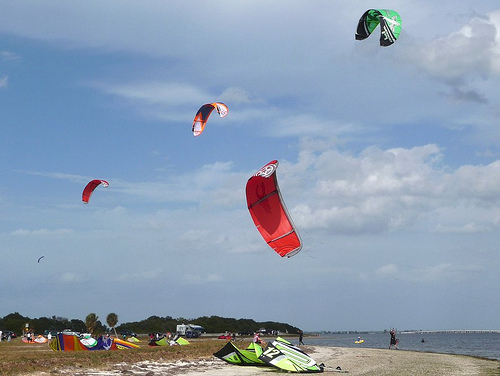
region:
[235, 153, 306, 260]
Red kite in the sky.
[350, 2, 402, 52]
Green and black kite in the sky.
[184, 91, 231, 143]
Orange kite in the sky.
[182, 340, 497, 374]
Sand on the ground.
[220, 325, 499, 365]
Water in the background.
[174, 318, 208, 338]
RV camper in the backgrund.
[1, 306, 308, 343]
Trees in the background.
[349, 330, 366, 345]
Boat in the water.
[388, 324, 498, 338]
Pier in the background.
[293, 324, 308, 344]
Person walking on the beach.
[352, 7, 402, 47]
a high flying green and black sail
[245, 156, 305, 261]
a low flying red and gray sail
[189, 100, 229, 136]
a colorful red black and orange sail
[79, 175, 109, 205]
a red and white sail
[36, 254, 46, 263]
a distant blue sail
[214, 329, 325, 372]
a pair of green sails on the beach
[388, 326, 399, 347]
a man walking on the beach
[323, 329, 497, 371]
a long beach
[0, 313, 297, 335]
a row of trees in the distance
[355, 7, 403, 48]
Kite flying in air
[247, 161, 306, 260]
Kite flying in air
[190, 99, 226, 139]
Kite flying in air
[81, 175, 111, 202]
Kite flying in air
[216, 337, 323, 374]
Kite lying on ground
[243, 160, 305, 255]
flying kite is red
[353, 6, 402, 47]
flying kite is green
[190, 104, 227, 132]
flying kite is orange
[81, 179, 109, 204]
flying kite is red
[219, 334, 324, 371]
kite on ground is green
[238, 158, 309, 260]
Bottom side of a red parasail.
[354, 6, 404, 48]
Green parasail flying in the air.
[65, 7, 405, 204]
A line of three parasails.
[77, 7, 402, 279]
Four parasails floating in the air.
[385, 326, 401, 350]
Man preparing to use a parasail.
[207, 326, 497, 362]
Body of water.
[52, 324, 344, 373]
Parasails laying on the beach.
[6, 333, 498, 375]
Beach area.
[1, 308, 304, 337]
Tree covered hills in the distance.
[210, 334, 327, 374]
Parasail with the number 12 on it.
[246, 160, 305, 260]
the kite is red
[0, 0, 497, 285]
clouds all over the sky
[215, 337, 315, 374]
kite on the ground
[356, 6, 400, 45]
green and black kite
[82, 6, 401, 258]
kites in the air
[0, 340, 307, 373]
short grass on beach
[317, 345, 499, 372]
sand on the shore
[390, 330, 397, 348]
man walking to water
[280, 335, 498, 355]
no waves in water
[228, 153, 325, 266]
parasail in the sky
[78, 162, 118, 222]
parasail in the sky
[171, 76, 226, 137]
parasail in the sky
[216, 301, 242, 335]
green leaves on the tree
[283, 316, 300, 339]
green leaves on the tree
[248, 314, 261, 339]
green leaves on the tree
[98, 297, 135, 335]
green leaves on the tree